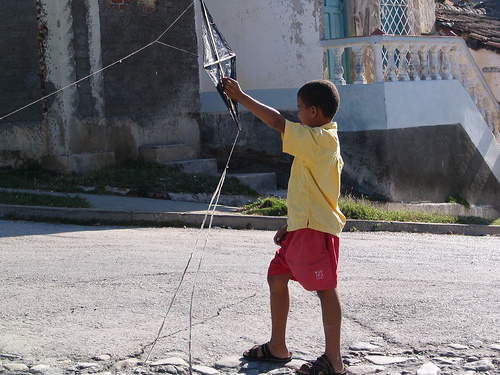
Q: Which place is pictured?
A: It is a road.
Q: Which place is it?
A: It is a road.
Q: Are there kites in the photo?
A: Yes, there is a kite.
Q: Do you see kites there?
A: Yes, there is a kite.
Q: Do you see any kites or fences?
A: Yes, there is a kite.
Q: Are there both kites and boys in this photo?
A: Yes, there are both a kite and a boy.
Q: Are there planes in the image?
A: No, there are no planes.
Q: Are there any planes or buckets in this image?
A: No, there are no planes or buckets.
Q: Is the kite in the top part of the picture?
A: Yes, the kite is in the top of the image.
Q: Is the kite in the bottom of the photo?
A: No, the kite is in the top of the image.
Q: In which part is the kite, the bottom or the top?
A: The kite is in the top of the image.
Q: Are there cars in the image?
A: No, there are no cars.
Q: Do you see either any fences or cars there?
A: No, there are no cars or fences.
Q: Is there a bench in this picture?
A: No, there are no benches.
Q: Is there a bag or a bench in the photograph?
A: No, there are no benches or bags.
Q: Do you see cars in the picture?
A: No, there are no cars.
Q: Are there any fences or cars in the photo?
A: No, there are no cars or fences.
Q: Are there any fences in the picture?
A: No, there are no fences.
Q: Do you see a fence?
A: No, there are no fences.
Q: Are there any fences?
A: No, there are no fences.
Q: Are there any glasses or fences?
A: No, there are no fences or glasses.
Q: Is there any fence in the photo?
A: No, there are no fences.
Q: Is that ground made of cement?
A: Yes, the ground is made of cement.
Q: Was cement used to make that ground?
A: Yes, the ground is made of cement.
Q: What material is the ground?
A: The ground is made of concrete.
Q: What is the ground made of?
A: The ground is made of concrete.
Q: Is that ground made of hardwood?
A: No, the ground is made of cement.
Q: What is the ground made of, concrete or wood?
A: The ground is made of concrete.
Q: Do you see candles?
A: No, there are no candles.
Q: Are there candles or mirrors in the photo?
A: No, there are no candles or mirrors.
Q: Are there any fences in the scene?
A: No, there are no fences.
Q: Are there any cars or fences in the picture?
A: No, there are no fences or cars.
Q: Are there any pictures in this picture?
A: No, there are no pictures.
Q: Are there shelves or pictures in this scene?
A: No, there are no pictures or shelves.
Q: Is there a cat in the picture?
A: No, there are no cats.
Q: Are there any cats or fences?
A: No, there are no cats or fences.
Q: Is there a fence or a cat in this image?
A: No, there are no cats or fences.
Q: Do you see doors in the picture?
A: Yes, there is a door.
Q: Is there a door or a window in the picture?
A: Yes, there is a door.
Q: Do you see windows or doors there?
A: Yes, there is a door.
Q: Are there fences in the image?
A: No, there are no fences.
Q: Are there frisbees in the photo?
A: No, there are no frisbees.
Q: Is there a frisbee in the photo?
A: No, there are no frisbees.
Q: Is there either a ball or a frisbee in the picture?
A: No, there are no frisbees or balls.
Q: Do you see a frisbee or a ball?
A: No, there are no frisbees or balls.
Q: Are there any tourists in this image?
A: No, there are no tourists.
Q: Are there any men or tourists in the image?
A: No, there are no tourists or men.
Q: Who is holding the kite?
A: The boy is holding the kite.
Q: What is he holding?
A: The boy is holding the kite.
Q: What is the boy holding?
A: The boy is holding the kite.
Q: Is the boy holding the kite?
A: Yes, the boy is holding the kite.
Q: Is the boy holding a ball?
A: No, the boy is holding the kite.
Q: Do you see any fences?
A: No, there are no fences.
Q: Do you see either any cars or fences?
A: No, there are no fences or cars.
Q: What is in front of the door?
A: The staircase is in front of the door.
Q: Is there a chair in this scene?
A: No, there are no chairs.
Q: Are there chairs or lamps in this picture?
A: No, there are no chairs or lamps.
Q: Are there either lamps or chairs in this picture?
A: No, there are no chairs or lamps.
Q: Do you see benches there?
A: No, there are no benches.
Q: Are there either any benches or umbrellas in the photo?
A: No, there are no benches or umbrellas.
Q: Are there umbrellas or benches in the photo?
A: No, there are no benches or umbrellas.